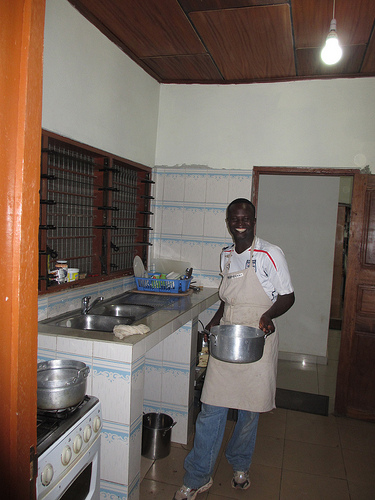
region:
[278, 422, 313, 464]
part of a floor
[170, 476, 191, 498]
part of a shoe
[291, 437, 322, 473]
part of a floor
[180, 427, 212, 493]
pat of a leg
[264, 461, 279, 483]
part of a floor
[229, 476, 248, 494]
edge of a shoe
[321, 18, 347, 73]
lightbulb hanging from the ceiling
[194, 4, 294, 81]
wood celing in room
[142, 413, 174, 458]
silver pot on the ground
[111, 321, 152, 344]
towel on the counter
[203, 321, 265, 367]
silver pot in man's hand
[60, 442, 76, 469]
knob on the stove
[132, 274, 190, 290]
dish drying tray on sink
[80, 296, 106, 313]
silver faucet on the sink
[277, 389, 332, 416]
rug on the floor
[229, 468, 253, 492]
left shoe on man's foot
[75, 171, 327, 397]
a cook in a kitchen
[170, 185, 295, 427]
this person is holding a pot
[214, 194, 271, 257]
this person is smiliing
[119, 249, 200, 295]
the dish drain is blue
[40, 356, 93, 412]
a poton the stove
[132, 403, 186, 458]
a pot under the sink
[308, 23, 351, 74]
a light on the ceiling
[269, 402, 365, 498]
tile on the floor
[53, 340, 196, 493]
a blue and white wall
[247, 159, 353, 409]
a doorway to a room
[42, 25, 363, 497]
The man is standing in a kitchen.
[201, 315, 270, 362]
The man is holding a pot.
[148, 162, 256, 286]
Tiles are on the wall.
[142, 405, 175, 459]
A pot is on the floor.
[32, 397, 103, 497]
The oven is white.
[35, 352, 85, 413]
A pan is on the oven.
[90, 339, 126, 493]
The tiles are blue and white.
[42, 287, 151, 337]
The sink has two basins in it.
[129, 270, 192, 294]
The dish drying rack is blue.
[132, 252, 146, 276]
A plate is sitting in the dish rack.